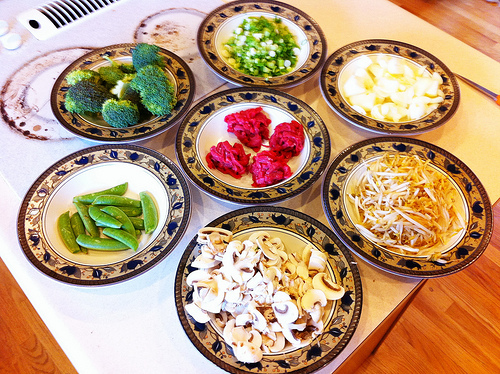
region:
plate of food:
[33, 160, 176, 285]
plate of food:
[200, 236, 335, 361]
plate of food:
[203, 103, 305, 196]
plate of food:
[61, 29, 170, 122]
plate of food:
[356, 37, 451, 134]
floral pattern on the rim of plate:
[198, 348, 352, 371]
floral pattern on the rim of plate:
[373, 243, 460, 283]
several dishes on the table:
[2, 5, 495, 367]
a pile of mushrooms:
[182, 207, 363, 372]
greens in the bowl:
[13, 141, 195, 303]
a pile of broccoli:
[55, 37, 198, 150]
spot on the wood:
[425, 283, 440, 298]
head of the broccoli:
[72, 79, 107, 111]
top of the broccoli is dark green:
[101, 105, 136, 129]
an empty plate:
[1, 49, 98, 146]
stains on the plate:
[139, 17, 199, 55]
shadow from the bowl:
[356, 262, 397, 284]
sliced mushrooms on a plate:
[188, 226, 345, 365]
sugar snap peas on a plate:
[56, 179, 156, 257]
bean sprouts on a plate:
[348, 150, 468, 260]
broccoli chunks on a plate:
[62, 42, 172, 136]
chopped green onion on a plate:
[223, 13, 304, 75]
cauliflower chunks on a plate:
[345, 54, 443, 119]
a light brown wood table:
[0, 0, 498, 370]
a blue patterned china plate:
[16, 142, 191, 282]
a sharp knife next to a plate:
[456, 72, 498, 105]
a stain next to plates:
[135, 4, 209, 65]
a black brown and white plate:
[15, 143, 192, 281]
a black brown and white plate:
[173, 206, 368, 372]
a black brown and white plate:
[320, 134, 491, 276]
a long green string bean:
[57, 209, 81, 253]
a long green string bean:
[70, 211, 87, 254]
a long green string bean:
[77, 233, 127, 248]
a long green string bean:
[103, 226, 138, 253]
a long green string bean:
[74, 202, 98, 237]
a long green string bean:
[90, 203, 120, 229]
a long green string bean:
[93, 194, 142, 207]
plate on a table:
[159, 202, 367, 372]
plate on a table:
[0, 121, 197, 299]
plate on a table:
[51, 27, 193, 143]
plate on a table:
[180, 78, 322, 198]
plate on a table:
[315, 136, 496, 282]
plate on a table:
[320, 37, 470, 139]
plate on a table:
[197, 0, 337, 87]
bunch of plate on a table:
[27, 6, 487, 368]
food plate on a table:
[153, 201, 374, 372]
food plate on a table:
[3, 119, 202, 304]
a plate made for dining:
[4, 37, 96, 146]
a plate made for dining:
[171, 194, 361, 372]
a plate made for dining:
[26, 134, 187, 276]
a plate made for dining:
[323, 123, 491, 286]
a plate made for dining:
[318, 31, 465, 132]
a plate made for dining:
[185, 81, 330, 199]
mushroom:
[228, 340, 271, 362]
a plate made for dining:
[192, 1, 330, 87]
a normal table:
[1, 1, 496, 371]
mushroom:
[310, 266, 348, 296]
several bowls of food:
[5, 7, 475, 369]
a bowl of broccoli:
[52, 40, 191, 137]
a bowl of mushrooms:
[191, 220, 356, 365]